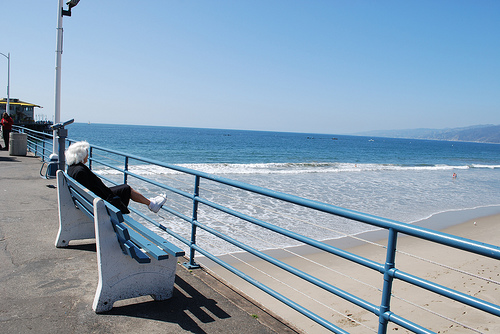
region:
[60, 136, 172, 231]
A woman watching the beach.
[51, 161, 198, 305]
The bench the woman is sitting on.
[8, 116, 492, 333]
A railing seperatin the sitting area from the beach.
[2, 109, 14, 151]
A person standing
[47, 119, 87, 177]
a telescope to look at the ocean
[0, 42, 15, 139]
a light pole.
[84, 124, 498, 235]
The ocean.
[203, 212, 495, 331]
The sandy beach.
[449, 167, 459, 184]
Someone standing in the ocean.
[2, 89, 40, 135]
Part of a building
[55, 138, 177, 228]
a woman with white hair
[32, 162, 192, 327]
a blue and white bench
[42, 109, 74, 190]
a look out telescope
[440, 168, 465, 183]
people swimming in the water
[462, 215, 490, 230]
a seagull on the beach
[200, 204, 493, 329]
the tan sandy beach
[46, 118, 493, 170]
the blue ocean water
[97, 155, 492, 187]
the ocean waves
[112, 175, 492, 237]
the shallow water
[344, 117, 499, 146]
the mountains in the distance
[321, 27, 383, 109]
part of the sky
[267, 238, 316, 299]
part of some metal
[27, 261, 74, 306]
part of a metal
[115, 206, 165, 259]
part of a bench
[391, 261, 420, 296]
part of a beach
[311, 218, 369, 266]
edge of a shore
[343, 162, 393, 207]
part of a water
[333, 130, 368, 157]
part of a water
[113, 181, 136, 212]
part of a skirt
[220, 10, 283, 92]
part of the sky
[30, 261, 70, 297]
part of a floor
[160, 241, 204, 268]
part of a bench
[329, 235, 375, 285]
part of a beach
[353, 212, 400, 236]
edge of a shore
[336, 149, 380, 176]
part of a water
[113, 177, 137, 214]
edge of a skirt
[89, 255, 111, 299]
edge of a bench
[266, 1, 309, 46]
part of the sky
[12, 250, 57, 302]
part of a floor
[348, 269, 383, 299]
part of a stand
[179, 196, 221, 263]
part of a post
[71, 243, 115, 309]
edge of a bench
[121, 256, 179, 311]
part of a bench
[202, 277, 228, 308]
part of a shade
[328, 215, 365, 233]
edge of a shore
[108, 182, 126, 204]
part of a skirt